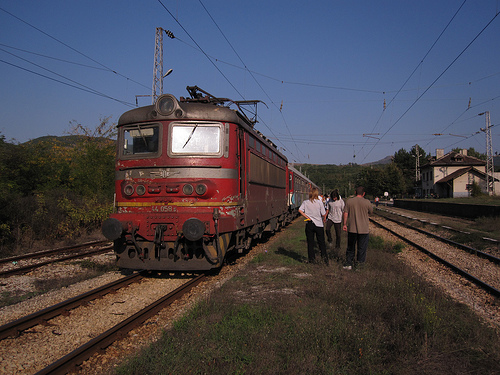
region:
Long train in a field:
[88, 84, 330, 281]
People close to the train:
[294, 174, 376, 272]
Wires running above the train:
[0, 0, 499, 107]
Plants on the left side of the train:
[1, 119, 111, 230]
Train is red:
[93, 87, 324, 282]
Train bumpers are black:
[94, 222, 230, 282]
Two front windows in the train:
[110, 116, 230, 168]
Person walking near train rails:
[366, 186, 385, 211]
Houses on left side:
[407, 136, 498, 210]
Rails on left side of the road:
[379, 205, 496, 321]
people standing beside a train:
[97, 72, 397, 278]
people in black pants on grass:
[290, 162, 381, 273]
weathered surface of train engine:
[110, 85, 265, 275]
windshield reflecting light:
[161, 120, 236, 160]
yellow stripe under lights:
[105, 180, 235, 210]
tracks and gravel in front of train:
[25, 215, 236, 368]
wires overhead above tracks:
[70, 40, 460, 100]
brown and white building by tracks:
[400, 137, 495, 204]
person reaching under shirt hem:
[286, 160, 326, 256]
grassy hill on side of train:
[18, 115, 138, 260]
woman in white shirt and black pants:
[289, 177, 336, 264]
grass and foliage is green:
[236, 305, 440, 373]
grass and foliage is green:
[206, 306, 428, 340]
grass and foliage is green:
[32, 115, 114, 213]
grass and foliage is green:
[261, 242, 423, 365]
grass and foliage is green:
[271, 286, 398, 326]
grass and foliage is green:
[333, 277, 448, 362]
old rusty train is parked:
[98, 82, 318, 270]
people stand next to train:
[298, 186, 375, 273]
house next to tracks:
[411, 147, 498, 199]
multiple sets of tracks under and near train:
[0, 205, 499, 374]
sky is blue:
[0, 0, 499, 165]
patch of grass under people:
[103, 215, 498, 374]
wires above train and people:
[0, 0, 499, 183]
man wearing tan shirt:
[343, 195, 375, 233]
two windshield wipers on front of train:
[136, 122, 198, 149]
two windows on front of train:
[120, 120, 224, 158]